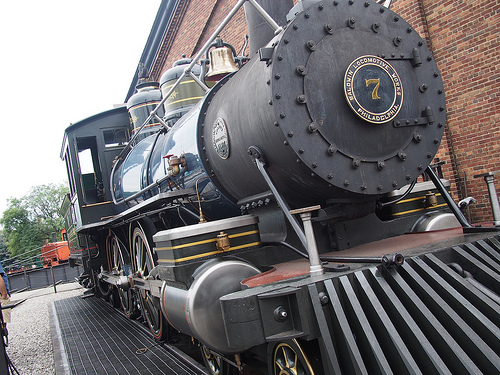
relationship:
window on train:
[100, 129, 130, 147] [58, 0, 498, 373]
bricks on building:
[452, 7, 492, 76] [111, 1, 496, 236]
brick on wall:
[438, 17, 473, 28] [148, 5, 483, 219]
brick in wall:
[442, 19, 485, 104] [446, 62, 490, 186]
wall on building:
[157, 0, 500, 223] [125, 0, 499, 253]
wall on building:
[124, 3, 495, 224] [125, 0, 499, 253]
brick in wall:
[462, 153, 472, 161] [454, 0, 494, 221]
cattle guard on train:
[308, 232, 498, 372] [58, 0, 498, 373]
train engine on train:
[57, 0, 498, 374] [58, 0, 498, 373]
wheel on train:
[131, 224, 163, 343] [58, 0, 498, 373]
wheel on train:
[105, 235, 135, 318] [58, 0, 498, 373]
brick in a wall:
[451, 68, 478, 86] [124, 3, 495, 224]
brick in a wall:
[453, 138, 468, 145] [124, 3, 495, 224]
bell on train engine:
[201, 38, 242, 79] [59, 0, 500, 375]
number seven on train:
[355, 72, 388, 104] [58, 0, 498, 373]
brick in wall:
[457, 122, 470, 130] [454, 80, 494, 154]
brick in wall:
[468, 103, 483, 118] [451, 26, 493, 166]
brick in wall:
[437, 60, 444, 67] [380, 0, 497, 224]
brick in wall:
[442, 78, 449, 86] [380, 0, 497, 224]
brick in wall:
[482, 78, 494, 86] [380, 0, 497, 224]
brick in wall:
[479, 52, 487, 59] [380, 0, 497, 224]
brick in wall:
[473, 83, 482, 90] [380, 0, 497, 224]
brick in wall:
[458, 125, 472, 129] [384, 1, 484, 213]